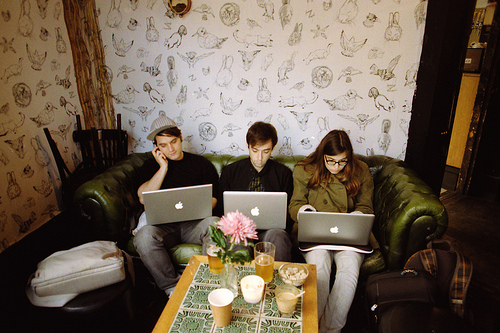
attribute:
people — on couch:
[125, 105, 388, 275]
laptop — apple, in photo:
[295, 204, 378, 248]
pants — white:
[295, 238, 371, 331]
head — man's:
[139, 100, 191, 166]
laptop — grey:
[297, 207, 375, 244]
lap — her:
[285, 202, 372, 280]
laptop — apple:
[295, 205, 370, 252]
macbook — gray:
[142, 178, 206, 219]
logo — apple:
[170, 195, 191, 218]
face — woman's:
[321, 149, 347, 175]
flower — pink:
[218, 211, 255, 244]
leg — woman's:
[330, 241, 352, 324]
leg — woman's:
[307, 247, 337, 324]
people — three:
[132, 110, 399, 255]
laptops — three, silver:
[140, 189, 380, 244]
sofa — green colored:
[93, 137, 437, 272]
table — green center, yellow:
[167, 246, 312, 332]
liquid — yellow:
[251, 260, 276, 280]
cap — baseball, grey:
[148, 118, 182, 136]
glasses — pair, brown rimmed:
[325, 152, 355, 170]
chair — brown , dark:
[45, 110, 125, 192]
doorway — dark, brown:
[424, 4, 495, 196]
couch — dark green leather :
[90, 142, 447, 301]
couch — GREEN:
[71, 142, 451, 285]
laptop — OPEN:
[140, 180, 217, 231]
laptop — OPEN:
[220, 188, 293, 236]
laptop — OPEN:
[292, 207, 377, 254]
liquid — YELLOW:
[257, 261, 269, 276]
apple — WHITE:
[325, 221, 345, 240]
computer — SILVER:
[295, 200, 378, 244]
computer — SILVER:
[220, 189, 290, 233]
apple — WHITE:
[249, 200, 263, 217]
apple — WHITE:
[170, 201, 187, 211]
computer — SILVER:
[140, 179, 220, 230]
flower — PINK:
[213, 210, 261, 244]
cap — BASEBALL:
[144, 110, 177, 147]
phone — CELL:
[150, 146, 167, 162]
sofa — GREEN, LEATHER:
[73, 150, 448, 268]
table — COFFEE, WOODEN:
[156, 252, 319, 327]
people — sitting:
[148, 140, 378, 270]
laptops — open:
[148, 182, 355, 272]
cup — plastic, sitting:
[205, 283, 233, 319]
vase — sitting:
[207, 249, 280, 319]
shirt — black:
[158, 148, 250, 186]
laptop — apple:
[130, 167, 229, 231]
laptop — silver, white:
[211, 170, 317, 251]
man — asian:
[221, 123, 305, 193]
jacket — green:
[270, 159, 382, 224]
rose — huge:
[185, 208, 305, 275]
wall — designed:
[124, 8, 390, 131]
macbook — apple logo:
[139, 180, 381, 264]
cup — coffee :
[200, 271, 303, 328]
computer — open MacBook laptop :
[135, 169, 385, 242]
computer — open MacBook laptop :
[132, 170, 390, 253]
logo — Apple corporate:
[131, 124, 394, 254]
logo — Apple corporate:
[153, 206, 352, 238]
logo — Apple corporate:
[167, 199, 354, 235]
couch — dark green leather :
[99, 150, 436, 282]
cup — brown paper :
[192, 274, 308, 324]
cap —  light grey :
[145, 103, 188, 165]